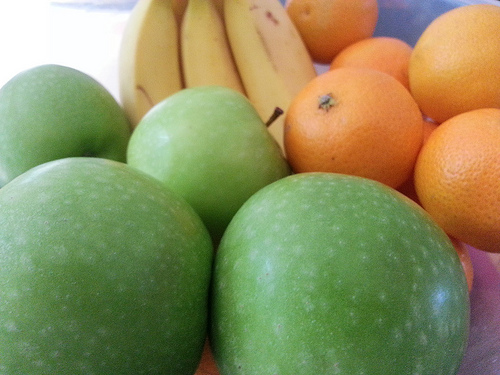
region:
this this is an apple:
[215, 156, 467, 371]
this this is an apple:
[4, 152, 223, 374]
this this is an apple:
[116, 81, 298, 205]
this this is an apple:
[0, 63, 131, 163]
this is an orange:
[413, 107, 496, 254]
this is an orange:
[286, 73, 430, 190]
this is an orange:
[332, 25, 409, 67]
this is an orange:
[400, 3, 498, 113]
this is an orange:
[294, 0, 374, 59]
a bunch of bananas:
[119, 0, 305, 145]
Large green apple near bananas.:
[41, 69, 108, 148]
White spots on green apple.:
[39, 180, 146, 315]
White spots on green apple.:
[273, 228, 377, 323]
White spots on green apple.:
[173, 97, 234, 174]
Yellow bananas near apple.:
[130, 32, 158, 108]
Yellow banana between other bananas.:
[196, 41, 221, 78]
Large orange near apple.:
[316, 82, 388, 174]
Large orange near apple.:
[433, 143, 495, 222]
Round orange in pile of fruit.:
[422, 42, 496, 102]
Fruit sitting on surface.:
[43, 45, 466, 296]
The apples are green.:
[0, 63, 469, 374]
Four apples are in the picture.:
[0, 62, 471, 374]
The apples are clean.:
[0, 63, 469, 373]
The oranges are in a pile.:
[282, 0, 497, 292]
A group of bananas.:
[118, 2, 322, 164]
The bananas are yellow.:
[116, 0, 321, 161]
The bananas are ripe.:
[116, 0, 321, 158]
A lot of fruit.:
[0, 1, 499, 373]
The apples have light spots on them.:
[0, 64, 472, 374]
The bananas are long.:
[116, 0, 318, 160]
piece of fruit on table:
[305, 84, 429, 167]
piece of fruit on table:
[228, 198, 455, 360]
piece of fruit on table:
[11, 174, 198, 341]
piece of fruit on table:
[158, 99, 268, 193]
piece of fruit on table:
[1, 67, 123, 153]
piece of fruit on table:
[428, 145, 492, 234]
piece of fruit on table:
[417, 24, 490, 99]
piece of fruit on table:
[339, 48, 409, 78]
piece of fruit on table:
[298, 0, 366, 41]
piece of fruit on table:
[106, 4, 294, 94]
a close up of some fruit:
[2, 1, 494, 371]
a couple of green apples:
[3, 61, 473, 373]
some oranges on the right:
[265, 0, 499, 257]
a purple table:
[417, 195, 496, 373]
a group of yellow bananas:
[112, 0, 324, 168]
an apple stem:
[255, 101, 292, 141]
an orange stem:
[308, 91, 343, 121]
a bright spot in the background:
[1, 0, 131, 112]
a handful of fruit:
[1, 1, 498, 373]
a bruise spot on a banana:
[245, 3, 292, 83]